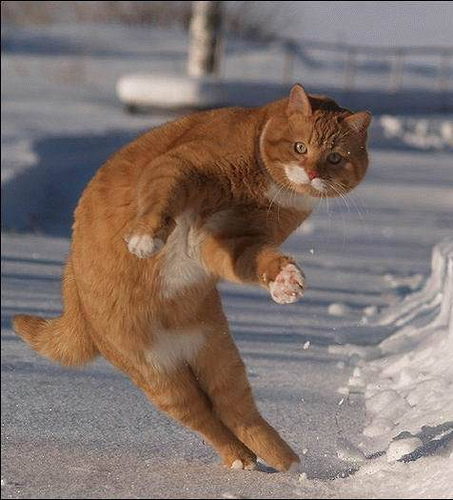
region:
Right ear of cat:
[282, 75, 308, 121]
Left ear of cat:
[338, 104, 373, 134]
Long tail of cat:
[8, 249, 94, 374]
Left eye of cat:
[330, 137, 349, 154]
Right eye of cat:
[286, 131, 304, 151]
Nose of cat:
[302, 160, 321, 179]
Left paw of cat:
[271, 247, 303, 314]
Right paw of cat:
[125, 227, 163, 255]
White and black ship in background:
[115, 49, 420, 114]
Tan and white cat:
[16, 81, 371, 474]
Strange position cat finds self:
[50, 86, 372, 482]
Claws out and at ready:
[207, 218, 325, 321]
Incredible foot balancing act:
[40, 260, 309, 482]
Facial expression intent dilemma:
[255, 92, 376, 220]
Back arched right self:
[70, 74, 255, 233]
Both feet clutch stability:
[155, 379, 321, 488]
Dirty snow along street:
[322, 225, 446, 498]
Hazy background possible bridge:
[255, 26, 451, 114]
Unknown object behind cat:
[105, 3, 266, 114]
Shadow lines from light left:
[0, 196, 415, 375]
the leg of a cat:
[125, 159, 200, 258]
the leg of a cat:
[232, 243, 320, 310]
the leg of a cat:
[187, 330, 300, 482]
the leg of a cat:
[151, 362, 260, 476]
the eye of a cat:
[292, 135, 310, 156]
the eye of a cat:
[329, 150, 343, 165]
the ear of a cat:
[283, 79, 310, 121]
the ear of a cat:
[344, 106, 375, 129]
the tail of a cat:
[8, 288, 91, 381]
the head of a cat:
[270, 81, 371, 210]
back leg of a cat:
[230, 389, 244, 434]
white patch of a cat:
[172, 328, 196, 359]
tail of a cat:
[57, 325, 79, 339]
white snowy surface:
[367, 383, 396, 436]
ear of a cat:
[353, 115, 374, 123]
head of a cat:
[279, 105, 370, 185]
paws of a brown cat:
[281, 271, 295, 294]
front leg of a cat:
[151, 169, 183, 219]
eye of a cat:
[329, 152, 342, 166]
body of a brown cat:
[225, 188, 259, 238]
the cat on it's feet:
[25, 52, 404, 471]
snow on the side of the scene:
[338, 284, 426, 465]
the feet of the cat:
[153, 357, 323, 474]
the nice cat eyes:
[289, 139, 356, 166]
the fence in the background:
[287, 35, 422, 86]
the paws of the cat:
[260, 259, 343, 321]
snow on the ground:
[24, 410, 97, 494]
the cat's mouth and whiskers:
[256, 158, 380, 226]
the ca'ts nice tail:
[3, 292, 94, 400]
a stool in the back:
[106, 65, 225, 108]